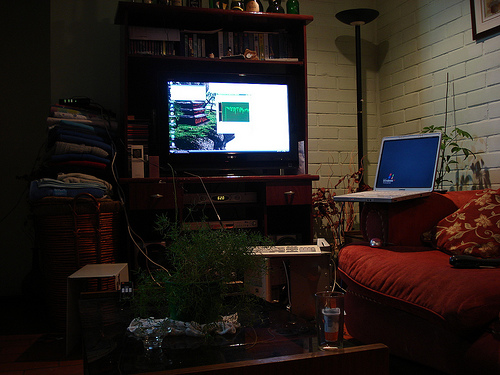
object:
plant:
[127, 204, 274, 359]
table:
[79, 328, 390, 374]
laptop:
[331, 133, 443, 203]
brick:
[306, 1, 498, 248]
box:
[58, 98, 78, 105]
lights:
[61, 98, 77, 103]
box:
[191, 191, 252, 203]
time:
[217, 196, 225, 201]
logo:
[383, 172, 395, 183]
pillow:
[435, 190, 498, 258]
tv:
[162, 75, 298, 177]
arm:
[360, 192, 458, 247]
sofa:
[337, 190, 499, 375]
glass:
[322, 259, 347, 350]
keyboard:
[336, 191, 433, 202]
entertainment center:
[113, 0, 320, 375]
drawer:
[264, 182, 313, 206]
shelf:
[135, 176, 320, 181]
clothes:
[32, 106, 117, 205]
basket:
[42, 193, 118, 292]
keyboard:
[251, 245, 321, 254]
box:
[245, 258, 333, 318]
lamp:
[335, 7, 379, 231]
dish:
[273, 323, 301, 336]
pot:
[126, 312, 244, 364]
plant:
[313, 156, 374, 291]